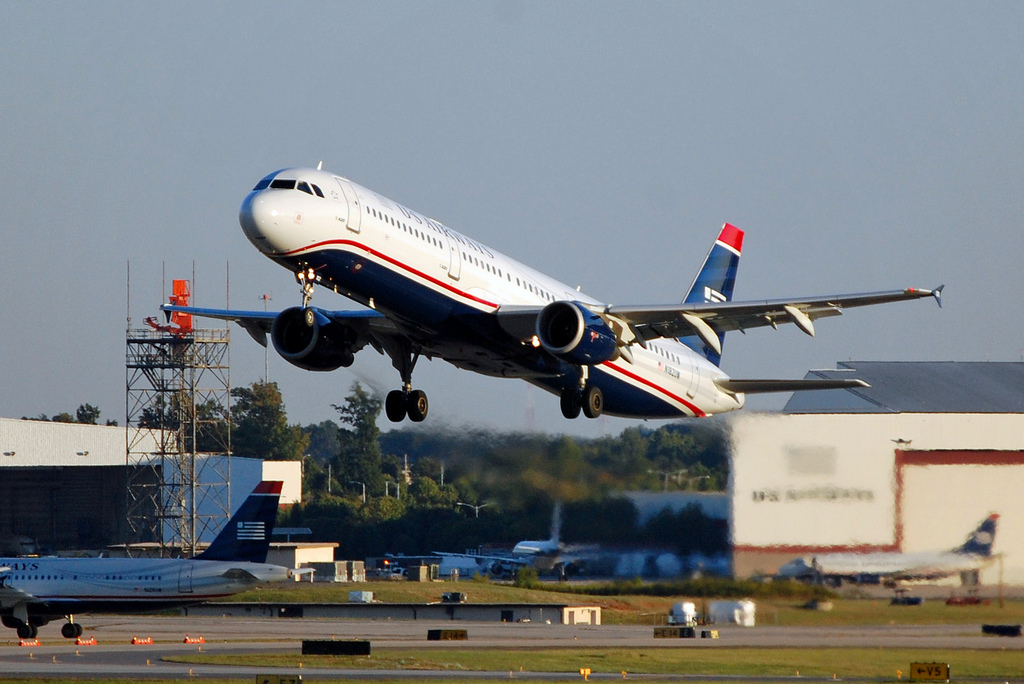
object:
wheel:
[384, 389, 436, 423]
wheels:
[580, 381, 604, 421]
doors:
[333, 176, 362, 234]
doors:
[444, 236, 461, 281]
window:
[269, 178, 295, 190]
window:
[297, 179, 314, 196]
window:
[310, 183, 325, 199]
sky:
[5, 3, 1023, 438]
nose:
[239, 155, 324, 259]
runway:
[2, 615, 1021, 654]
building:
[725, 358, 1021, 582]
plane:
[774, 507, 999, 593]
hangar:
[726, 360, 1022, 585]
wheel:
[556, 377, 609, 420]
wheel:
[295, 302, 321, 328]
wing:
[161, 299, 388, 371]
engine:
[269, 304, 360, 371]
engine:
[534, 297, 622, 368]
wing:
[496, 284, 948, 365]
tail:
[195, 477, 282, 563]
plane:
[0, 545, 316, 642]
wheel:
[58, 608, 85, 643]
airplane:
[161, 159, 949, 423]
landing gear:
[383, 386, 431, 424]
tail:
[662, 220, 743, 368]